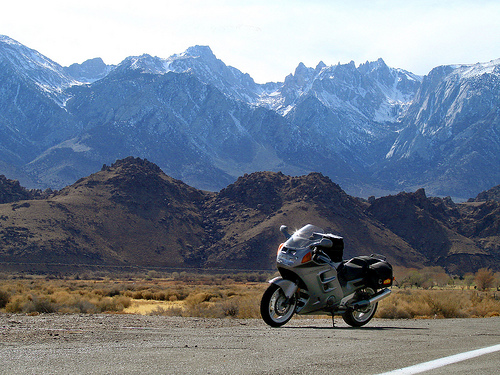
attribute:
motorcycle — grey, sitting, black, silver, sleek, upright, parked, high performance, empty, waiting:
[258, 222, 396, 337]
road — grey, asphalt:
[1, 309, 500, 373]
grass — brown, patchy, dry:
[1, 274, 498, 318]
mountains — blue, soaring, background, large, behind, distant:
[2, 36, 499, 198]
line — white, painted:
[374, 341, 499, 371]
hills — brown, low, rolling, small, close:
[1, 155, 500, 291]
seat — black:
[337, 257, 375, 281]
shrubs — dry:
[22, 293, 236, 318]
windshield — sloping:
[284, 223, 322, 249]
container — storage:
[366, 262, 393, 288]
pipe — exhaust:
[351, 289, 391, 306]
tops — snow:
[2, 37, 498, 120]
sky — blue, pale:
[6, 1, 499, 74]